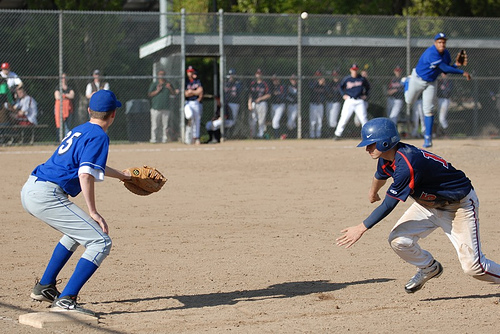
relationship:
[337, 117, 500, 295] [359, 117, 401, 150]
kid wearing helmet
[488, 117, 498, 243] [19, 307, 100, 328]
kid running to base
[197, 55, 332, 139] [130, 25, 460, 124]
kid sitting in a dug out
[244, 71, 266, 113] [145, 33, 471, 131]
kid standing in a dug out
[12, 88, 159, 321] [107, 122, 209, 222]
kid holding catchers mitt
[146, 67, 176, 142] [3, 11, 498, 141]
guy holding onto a fence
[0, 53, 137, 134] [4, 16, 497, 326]
people watching a baseball